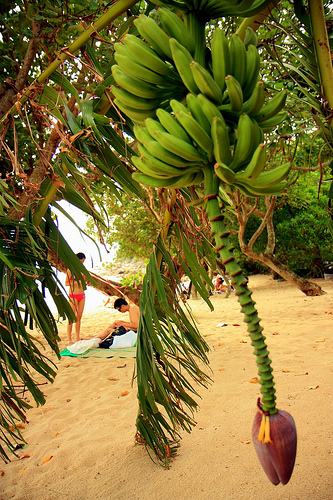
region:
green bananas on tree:
[109, 9, 290, 183]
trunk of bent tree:
[236, 213, 325, 295]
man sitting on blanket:
[62, 297, 138, 356]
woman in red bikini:
[64, 252, 86, 344]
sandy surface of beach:
[2, 276, 331, 499]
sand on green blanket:
[59, 349, 137, 359]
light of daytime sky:
[54, 203, 112, 261]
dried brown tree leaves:
[47, 111, 95, 173]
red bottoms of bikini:
[68, 292, 85, 302]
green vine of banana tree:
[203, 183, 275, 409]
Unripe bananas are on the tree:
[88, 6, 319, 215]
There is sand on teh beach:
[70, 367, 233, 485]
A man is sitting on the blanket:
[68, 277, 192, 419]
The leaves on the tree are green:
[151, 270, 298, 443]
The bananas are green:
[123, 138, 327, 304]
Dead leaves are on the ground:
[4, 360, 169, 491]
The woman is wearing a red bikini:
[56, 261, 134, 361]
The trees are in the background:
[99, 190, 255, 364]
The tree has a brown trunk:
[208, 210, 331, 298]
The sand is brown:
[52, 407, 142, 496]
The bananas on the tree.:
[105, 18, 296, 202]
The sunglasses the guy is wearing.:
[115, 303, 123, 313]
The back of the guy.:
[127, 308, 140, 324]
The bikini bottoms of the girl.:
[69, 290, 86, 302]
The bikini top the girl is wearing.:
[68, 266, 86, 282]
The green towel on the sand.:
[62, 340, 160, 361]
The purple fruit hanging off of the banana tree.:
[208, 192, 296, 480]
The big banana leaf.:
[134, 198, 206, 466]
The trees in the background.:
[93, 131, 331, 284]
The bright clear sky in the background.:
[52, 205, 122, 308]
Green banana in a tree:
[145, 123, 186, 162]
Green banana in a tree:
[222, 149, 286, 212]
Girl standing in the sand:
[59, 246, 92, 364]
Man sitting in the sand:
[93, 283, 153, 372]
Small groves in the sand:
[46, 457, 105, 497]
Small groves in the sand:
[111, 455, 198, 496]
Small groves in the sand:
[196, 399, 246, 447]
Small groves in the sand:
[275, 350, 318, 409]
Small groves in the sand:
[56, 369, 130, 398]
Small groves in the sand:
[200, 325, 231, 399]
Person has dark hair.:
[112, 296, 126, 312]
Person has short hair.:
[109, 292, 129, 302]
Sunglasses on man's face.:
[113, 304, 125, 317]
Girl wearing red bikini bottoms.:
[63, 290, 106, 307]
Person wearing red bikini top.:
[66, 269, 100, 283]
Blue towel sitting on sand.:
[65, 336, 123, 373]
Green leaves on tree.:
[135, 401, 156, 442]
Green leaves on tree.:
[146, 333, 171, 362]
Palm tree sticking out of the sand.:
[288, 273, 318, 291]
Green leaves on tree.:
[42, 283, 70, 311]